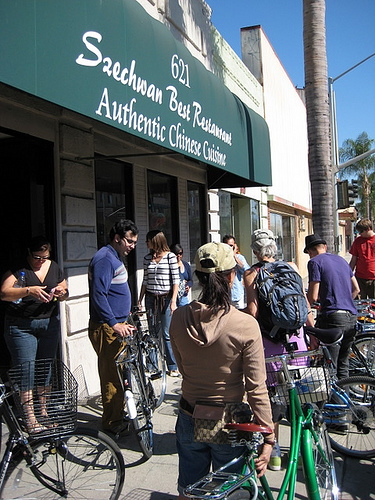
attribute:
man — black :
[301, 230, 361, 433]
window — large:
[266, 207, 304, 270]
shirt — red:
[348, 240, 373, 273]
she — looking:
[2, 237, 68, 434]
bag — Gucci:
[190, 399, 248, 445]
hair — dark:
[191, 250, 239, 318]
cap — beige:
[194, 240, 237, 272]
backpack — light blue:
[258, 261, 308, 336]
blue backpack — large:
[232, 252, 302, 329]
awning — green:
[0, 0, 274, 192]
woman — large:
[2, 239, 68, 435]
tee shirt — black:
[11, 258, 64, 318]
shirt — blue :
[92, 238, 133, 322]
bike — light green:
[201, 364, 332, 499]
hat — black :
[299, 232, 330, 251]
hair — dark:
[15, 227, 57, 265]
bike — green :
[240, 375, 346, 482]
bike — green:
[182, 339, 343, 498]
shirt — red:
[348, 237, 374, 281]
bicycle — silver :
[217, 365, 370, 479]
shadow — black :
[83, 408, 193, 453]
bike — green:
[169, 337, 357, 497]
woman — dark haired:
[166, 233, 284, 499]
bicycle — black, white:
[254, 375, 355, 489]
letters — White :
[77, 28, 232, 166]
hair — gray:
[250, 227, 275, 260]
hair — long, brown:
[143, 226, 169, 256]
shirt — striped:
[143, 249, 172, 300]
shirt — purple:
[306, 259, 351, 313]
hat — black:
[299, 230, 326, 251]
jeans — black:
[318, 308, 350, 389]